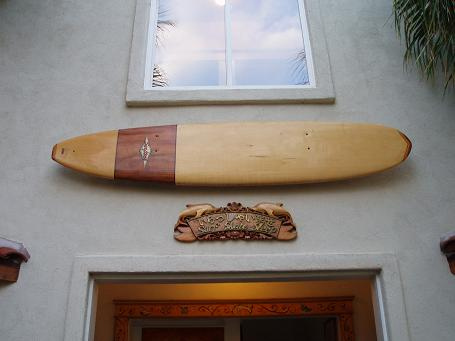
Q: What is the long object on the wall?
A: A surfboard.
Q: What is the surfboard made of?
A: Wood.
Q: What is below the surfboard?
A: A sign.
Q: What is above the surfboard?
A: A window.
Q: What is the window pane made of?
A: Glass.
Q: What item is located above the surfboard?
A: Window.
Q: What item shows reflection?
A: Window.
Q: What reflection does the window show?
A: Cloudy sky.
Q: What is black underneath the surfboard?
A: Shadow of surfboard.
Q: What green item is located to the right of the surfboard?
A: Tree.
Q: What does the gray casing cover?
A: Window.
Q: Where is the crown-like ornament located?
A: Beneath the surfboard.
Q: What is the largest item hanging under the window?
A: Surfboard.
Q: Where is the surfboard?
A: On the wall.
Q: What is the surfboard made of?
A: Wood.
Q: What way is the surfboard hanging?
A: Horizontally.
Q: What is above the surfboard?
A: Window.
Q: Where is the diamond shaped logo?
A: On surfboard.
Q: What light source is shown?
A: Sun.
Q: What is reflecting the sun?
A: Window.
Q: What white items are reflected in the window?
A: Clouds.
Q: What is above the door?
A: Surfboard.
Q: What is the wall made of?
A: Cement.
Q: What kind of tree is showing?
A: Palm.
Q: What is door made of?
A: Wood.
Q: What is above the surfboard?
A: Window.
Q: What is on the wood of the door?
A: Carvings.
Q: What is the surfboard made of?
A: Wood.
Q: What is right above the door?
A: Wood carving.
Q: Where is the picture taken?
A: Front of a building.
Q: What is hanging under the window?
A: A surfboard.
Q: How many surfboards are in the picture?
A: One.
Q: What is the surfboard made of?
A: Wood.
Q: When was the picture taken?
A: Daytime.